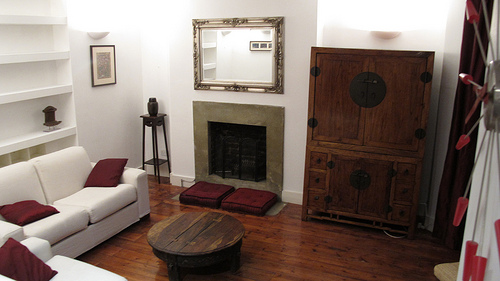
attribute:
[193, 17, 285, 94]
mirror — large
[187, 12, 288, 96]
mirror — rectangular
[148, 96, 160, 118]
vase — small, black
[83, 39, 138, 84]
picture — framed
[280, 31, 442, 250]
wooden chest — large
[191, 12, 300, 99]
mirror — large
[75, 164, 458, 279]
floor — hardwoord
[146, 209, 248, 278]
table — circular, dark, wooden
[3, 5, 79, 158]
shelf — white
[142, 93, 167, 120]
vase — black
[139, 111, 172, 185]
stand — small, dark, tall, black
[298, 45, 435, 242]
cabinet — wooden, dark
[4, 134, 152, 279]
couch — white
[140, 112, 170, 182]
table — dark, wooden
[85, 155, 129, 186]
pillow — dark red, burgundy, square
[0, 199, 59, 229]
pillow — burgundy, square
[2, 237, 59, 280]
pillow — burgundy, square